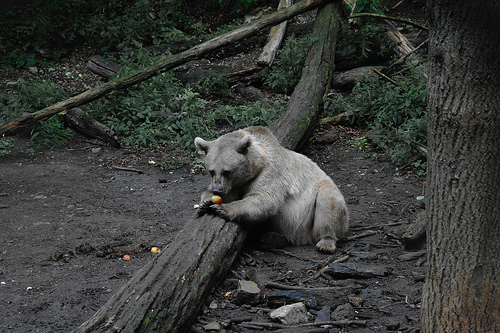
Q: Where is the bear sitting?
A: On the ground.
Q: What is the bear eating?
A: Fruit.